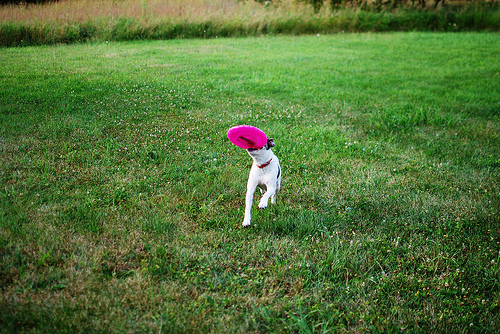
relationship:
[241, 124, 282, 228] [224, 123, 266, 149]
dog catching frisbee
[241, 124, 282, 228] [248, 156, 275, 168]
dog wearing collar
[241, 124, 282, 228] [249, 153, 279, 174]
dog wearing collar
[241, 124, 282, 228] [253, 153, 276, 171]
dog wearing collar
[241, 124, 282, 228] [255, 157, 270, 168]
dog wearing collar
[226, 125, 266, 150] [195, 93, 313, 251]
frisbee caught by dog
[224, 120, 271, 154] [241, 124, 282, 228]
frisbee caught by dog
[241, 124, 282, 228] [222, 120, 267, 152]
dog with frisbee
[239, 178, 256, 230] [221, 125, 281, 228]
leg of dog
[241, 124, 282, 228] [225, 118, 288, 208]
dog playing with playing frisbee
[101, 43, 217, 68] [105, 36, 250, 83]
spots in field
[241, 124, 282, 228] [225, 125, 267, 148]
dog with frisbee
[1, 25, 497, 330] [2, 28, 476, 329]
grass on lawn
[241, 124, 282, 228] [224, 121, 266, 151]
dog carrying frisbee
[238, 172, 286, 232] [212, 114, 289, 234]
feet on dog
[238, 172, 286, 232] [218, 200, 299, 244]
feet off ground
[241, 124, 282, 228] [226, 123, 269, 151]
dog running with frisbee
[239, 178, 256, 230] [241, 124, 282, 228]
leg on dog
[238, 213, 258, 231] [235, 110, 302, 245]
paw on dog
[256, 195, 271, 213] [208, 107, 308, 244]
paw on dog